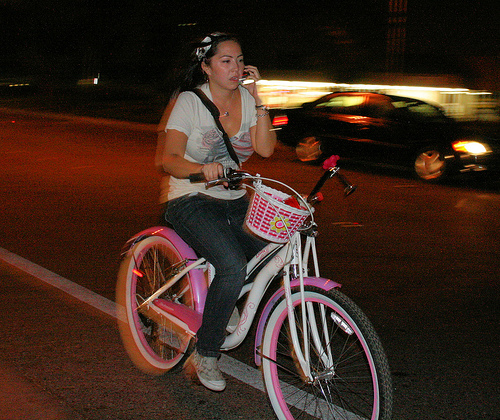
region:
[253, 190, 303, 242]
basket on the bike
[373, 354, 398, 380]
front tire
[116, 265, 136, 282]
the back tire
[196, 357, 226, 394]
the womens shoe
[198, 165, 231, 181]
women holding handle bar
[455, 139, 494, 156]
headlight on the car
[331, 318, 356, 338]
reflector on the tire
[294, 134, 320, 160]
back tire on the car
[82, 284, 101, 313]
white line on the street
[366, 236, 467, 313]
the street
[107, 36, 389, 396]
a woman riding a pink bike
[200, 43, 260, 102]
a woman using a cell phone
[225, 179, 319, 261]
a basket attached to a bike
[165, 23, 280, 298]
a woman using a cell phone while riding a bike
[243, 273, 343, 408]
a pink fender on a bike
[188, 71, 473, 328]
a car on the road next to a bike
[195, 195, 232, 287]
a woman wearing jeans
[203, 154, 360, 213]
handle bars on a bike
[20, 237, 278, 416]
a white line painted on a roadway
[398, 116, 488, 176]
a car with the headlights on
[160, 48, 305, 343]
woman on pink bike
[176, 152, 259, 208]
right hand on woman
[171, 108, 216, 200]
right arm on woman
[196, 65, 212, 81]
right ear on woman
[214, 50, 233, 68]
right eye on woman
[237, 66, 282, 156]
left arm on woman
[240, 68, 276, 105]
left hand on woman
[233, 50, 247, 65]
left eye on woman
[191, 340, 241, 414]
right foot on woman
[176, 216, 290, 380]
right leg on woman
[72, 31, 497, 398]
a woman ridng a bike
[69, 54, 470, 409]
a woman riding a bike on the road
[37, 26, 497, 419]
a woman riding a bike on the street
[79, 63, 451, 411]
a woman riding a bike at night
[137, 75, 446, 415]
a woman on a pink bike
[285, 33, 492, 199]
a vehicle on the road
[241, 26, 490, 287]
a vehcle on the street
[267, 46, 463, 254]
a black car on the road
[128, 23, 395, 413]
Woman in a bicycle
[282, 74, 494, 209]
Car on the pavement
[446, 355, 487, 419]
PArt of the road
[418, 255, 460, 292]
PArt of the road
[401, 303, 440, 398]
PArt of the road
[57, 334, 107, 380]
PArt of the road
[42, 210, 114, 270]
PArt of the road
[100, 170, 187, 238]
PArt of the road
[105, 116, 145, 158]
PArt of the road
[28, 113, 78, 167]
PArt of the road